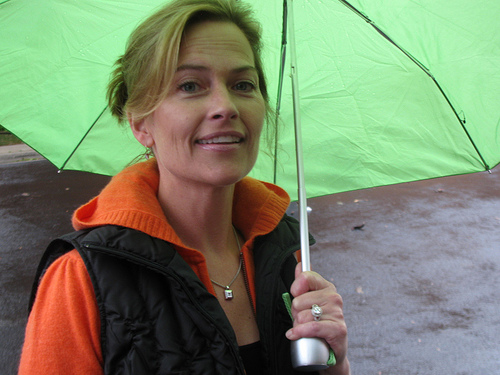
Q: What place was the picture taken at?
A: It was taken at the street.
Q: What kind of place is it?
A: It is a street.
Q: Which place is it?
A: It is a street.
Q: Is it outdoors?
A: Yes, it is outdoors.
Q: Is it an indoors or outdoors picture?
A: It is outdoors.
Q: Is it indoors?
A: No, it is outdoors.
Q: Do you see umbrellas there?
A: Yes, there is an umbrella.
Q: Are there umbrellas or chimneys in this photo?
A: Yes, there is an umbrella.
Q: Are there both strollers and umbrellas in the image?
A: No, there is an umbrella but no strollers.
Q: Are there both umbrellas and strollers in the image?
A: No, there is an umbrella but no strollers.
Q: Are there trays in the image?
A: No, there are no trays.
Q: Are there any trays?
A: No, there are no trays.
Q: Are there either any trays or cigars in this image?
A: No, there are no trays or cigars.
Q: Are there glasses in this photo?
A: No, there are no glasses.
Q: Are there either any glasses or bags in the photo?
A: No, there are no glasses or bags.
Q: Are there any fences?
A: No, there are no fences.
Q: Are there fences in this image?
A: No, there are no fences.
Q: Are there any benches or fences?
A: No, there are no fences or benches.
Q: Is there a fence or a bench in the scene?
A: No, there are no fences or benches.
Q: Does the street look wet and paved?
A: Yes, the street is wet and paved.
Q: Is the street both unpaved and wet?
A: No, the street is wet but paved.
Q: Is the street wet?
A: Yes, the street is wet.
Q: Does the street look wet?
A: Yes, the street is wet.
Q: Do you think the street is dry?
A: No, the street is wet.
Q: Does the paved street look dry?
A: No, the street is wet.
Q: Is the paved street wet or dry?
A: The street is wet.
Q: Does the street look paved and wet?
A: Yes, the street is paved and wet.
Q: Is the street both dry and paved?
A: No, the street is paved but wet.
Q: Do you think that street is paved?
A: Yes, the street is paved.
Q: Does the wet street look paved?
A: Yes, the street is paved.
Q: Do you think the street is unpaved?
A: No, the street is paved.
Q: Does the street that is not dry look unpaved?
A: No, the street is paved.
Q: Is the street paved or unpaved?
A: The street is paved.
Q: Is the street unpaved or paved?
A: The street is paved.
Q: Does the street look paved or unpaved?
A: The street is paved.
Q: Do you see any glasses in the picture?
A: No, there are no glasses.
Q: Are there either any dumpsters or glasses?
A: No, there are no glasses or dumpsters.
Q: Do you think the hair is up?
A: Yes, the hair is up.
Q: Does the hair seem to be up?
A: Yes, the hair is up.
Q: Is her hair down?
A: No, the hair is up.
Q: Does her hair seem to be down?
A: No, the hair is up.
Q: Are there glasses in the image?
A: No, there are no glasses.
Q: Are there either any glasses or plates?
A: No, there are no glasses or plates.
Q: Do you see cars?
A: No, there are no cars.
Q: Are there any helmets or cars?
A: No, there are no cars or helmets.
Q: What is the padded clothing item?
A: The clothing item is a vest.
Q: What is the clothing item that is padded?
A: The clothing item is a vest.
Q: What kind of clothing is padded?
A: The clothing is a vest.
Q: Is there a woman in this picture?
A: Yes, there is a woman.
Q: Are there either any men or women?
A: Yes, there is a woman.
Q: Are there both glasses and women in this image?
A: No, there is a woman but no glasses.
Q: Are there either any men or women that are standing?
A: Yes, the woman is standing.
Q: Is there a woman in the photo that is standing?
A: Yes, there is a woman that is standing.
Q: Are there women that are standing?
A: Yes, there is a woman that is standing.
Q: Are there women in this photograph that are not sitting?
A: Yes, there is a woman that is standing.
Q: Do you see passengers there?
A: No, there are no passengers.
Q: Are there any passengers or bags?
A: No, there are no passengers or bags.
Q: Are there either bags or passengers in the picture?
A: No, there are no passengers or bags.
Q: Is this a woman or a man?
A: This is a woman.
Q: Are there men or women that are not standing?
A: No, there is a woman but she is standing.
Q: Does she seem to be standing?
A: Yes, the woman is standing.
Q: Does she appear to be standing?
A: Yes, the woman is standing.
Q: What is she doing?
A: The woman is standing.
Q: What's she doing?
A: The woman is standing.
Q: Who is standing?
A: The woman is standing.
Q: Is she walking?
A: No, the woman is standing.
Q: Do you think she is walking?
A: No, the woman is standing.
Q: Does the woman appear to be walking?
A: No, the woman is standing.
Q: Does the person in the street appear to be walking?
A: No, the woman is standing.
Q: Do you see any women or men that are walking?
A: No, there is a woman but she is standing.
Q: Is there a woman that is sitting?
A: No, there is a woman but she is standing.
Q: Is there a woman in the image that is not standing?
A: No, there is a woman but she is standing.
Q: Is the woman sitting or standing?
A: The woman is standing.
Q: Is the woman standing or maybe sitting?
A: The woman is standing.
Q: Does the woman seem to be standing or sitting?
A: The woman is standing.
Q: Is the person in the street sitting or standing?
A: The woman is standing.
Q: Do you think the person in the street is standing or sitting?
A: The woman is standing.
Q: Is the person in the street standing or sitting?
A: The woman is standing.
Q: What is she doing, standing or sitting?
A: The woman is standing.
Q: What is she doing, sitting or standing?
A: The woman is standing.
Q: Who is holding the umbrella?
A: The woman is holding the umbrella.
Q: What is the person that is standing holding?
A: The woman is holding the umbrella.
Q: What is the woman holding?
A: The woman is holding the umbrella.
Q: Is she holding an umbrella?
A: Yes, the woman is holding an umbrella.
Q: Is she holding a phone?
A: No, the woman is holding an umbrella.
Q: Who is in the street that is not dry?
A: The woman is in the street.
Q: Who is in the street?
A: The woman is in the street.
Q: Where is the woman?
A: The woman is in the street.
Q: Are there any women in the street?
A: Yes, there is a woman in the street.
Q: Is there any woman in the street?
A: Yes, there is a woman in the street.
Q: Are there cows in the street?
A: No, there is a woman in the street.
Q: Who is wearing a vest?
A: The woman is wearing a vest.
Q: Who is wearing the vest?
A: The woman is wearing a vest.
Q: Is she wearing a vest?
A: Yes, the woman is wearing a vest.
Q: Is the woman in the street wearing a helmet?
A: No, the woman is wearing a vest.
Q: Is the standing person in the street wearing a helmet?
A: No, the woman is wearing a vest.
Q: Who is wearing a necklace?
A: The woman is wearing a necklace.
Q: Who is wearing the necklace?
A: The woman is wearing a necklace.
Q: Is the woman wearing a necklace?
A: Yes, the woman is wearing a necklace.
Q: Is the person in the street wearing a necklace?
A: Yes, the woman is wearing a necklace.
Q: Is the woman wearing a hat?
A: No, the woman is wearing a necklace.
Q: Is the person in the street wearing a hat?
A: No, the woman is wearing a necklace.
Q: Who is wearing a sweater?
A: The woman is wearing a sweater.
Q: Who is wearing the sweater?
A: The woman is wearing a sweater.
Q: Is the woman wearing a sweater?
A: Yes, the woman is wearing a sweater.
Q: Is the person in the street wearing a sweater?
A: Yes, the woman is wearing a sweater.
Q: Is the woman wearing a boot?
A: No, the woman is wearing a sweater.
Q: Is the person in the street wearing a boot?
A: No, the woman is wearing a sweater.